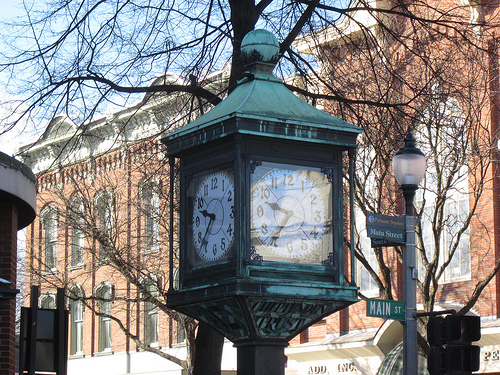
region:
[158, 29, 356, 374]
Large clock with two visible faces.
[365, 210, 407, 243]
Two signs at the top of a light pole.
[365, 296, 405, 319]
Green street sign that reads MAIN ST.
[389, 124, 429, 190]
Very top of a light pole on the right.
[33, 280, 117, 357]
Bottom left three windows.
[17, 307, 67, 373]
Back of a large sign on the left bottom.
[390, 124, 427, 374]
Light pole to the right of a clock.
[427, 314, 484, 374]
Cross walk device to the bottom right of the clock.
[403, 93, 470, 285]
Large arched window with multiple panes.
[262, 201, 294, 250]
Black hands on the right side clock face.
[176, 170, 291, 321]
White face on clock.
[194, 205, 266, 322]
Clock has dark numbers.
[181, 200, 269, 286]
Clock has black hands.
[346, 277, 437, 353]
Green street sign with white writing.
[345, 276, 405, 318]
Street sign says MAIN st.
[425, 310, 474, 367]
Black crosswalk signal.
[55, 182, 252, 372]
Large brick building across the street.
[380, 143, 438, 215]
Light on top of pole over street sign.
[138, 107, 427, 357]
Tree behind the clocks.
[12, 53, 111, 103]
Sky is blue with a few clouds.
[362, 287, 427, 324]
a sign for main street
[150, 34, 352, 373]
an old looking clock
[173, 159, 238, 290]
a clock showing 9:35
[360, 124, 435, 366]
a post with a street light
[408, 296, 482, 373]
a pedestrian light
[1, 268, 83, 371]
the backside of a sign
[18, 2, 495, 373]
a clock in front of a large building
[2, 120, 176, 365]
a building made of bricks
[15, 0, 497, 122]
a tree with no leaves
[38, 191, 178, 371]
eight windows on a brick building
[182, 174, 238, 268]
white and black clock face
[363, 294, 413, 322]
sign marking main street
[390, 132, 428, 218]
gas street lamp with black top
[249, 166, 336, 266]
clock marking time at 9:36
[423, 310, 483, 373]
street crossing sign with red light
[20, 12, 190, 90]
tree branch bare of leaves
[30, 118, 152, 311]
two story brick building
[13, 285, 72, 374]
rear of street sign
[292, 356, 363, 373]
Add Inc written on overhang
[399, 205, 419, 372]
grey lamp post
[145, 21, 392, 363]
decorative clock on a city street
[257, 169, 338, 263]
white face of a clock behind glass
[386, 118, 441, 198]
street light on a lamp post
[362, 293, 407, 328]
green rectangular street sign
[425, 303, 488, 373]
traffic lights attached to pole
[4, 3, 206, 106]
bare branches of a tree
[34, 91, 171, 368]
building in the background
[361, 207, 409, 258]
street signs attached to pole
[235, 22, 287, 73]
top circle part of clock tower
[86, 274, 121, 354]
window of a building in the background